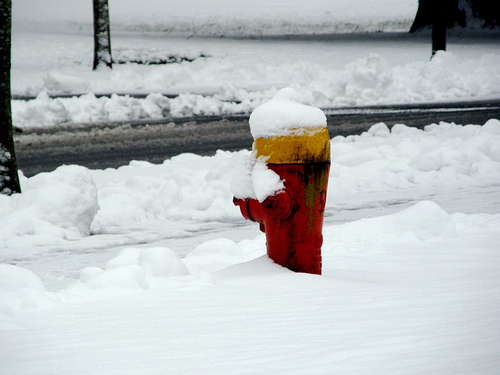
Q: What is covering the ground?
A: Snow.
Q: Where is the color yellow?
A: Top of the fire hydrant.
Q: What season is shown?
A: Winter.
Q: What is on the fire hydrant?
A: Snow.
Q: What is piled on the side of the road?
A: Snow.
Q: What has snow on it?
A: The fire hydrant.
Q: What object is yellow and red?
A: The fire hydrant.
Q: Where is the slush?
A: Side of the street.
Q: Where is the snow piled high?
A: At the curb?.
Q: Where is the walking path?
A: Through the snow.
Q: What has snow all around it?
A: The fire hydrant.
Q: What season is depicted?
A: Winter.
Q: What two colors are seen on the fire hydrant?
A: Red and yellow.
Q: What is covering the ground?
A: Snow.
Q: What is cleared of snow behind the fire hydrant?
A: Road.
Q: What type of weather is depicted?
A: Overcast and cold.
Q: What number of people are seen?
A: Zero.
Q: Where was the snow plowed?
A: On the road behind the hydrant.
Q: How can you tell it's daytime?
A: Shadows near the trees.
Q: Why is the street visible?
A: It was plowed.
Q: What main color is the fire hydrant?
A: Red.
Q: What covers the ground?
A: Snow.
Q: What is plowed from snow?
A: Sidewalk.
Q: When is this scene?
A: Afternoon.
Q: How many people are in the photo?
A: None.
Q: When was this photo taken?
A: During the day.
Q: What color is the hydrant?
A: Red.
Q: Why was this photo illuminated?
A: Sunlight.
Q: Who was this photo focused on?
A: The hydrant.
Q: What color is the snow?
A: White.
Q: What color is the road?
A: Gray.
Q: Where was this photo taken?
A: On a snowy sidewalk.